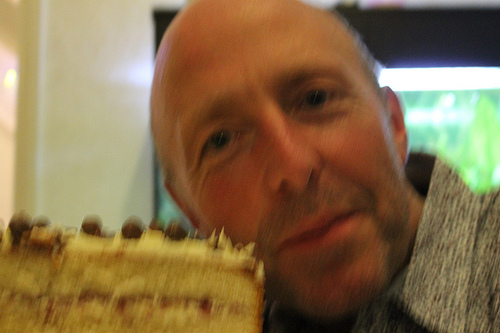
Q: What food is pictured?
A: Cake.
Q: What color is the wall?
A: White.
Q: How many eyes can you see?
A: 2.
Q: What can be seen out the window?
A: Trees.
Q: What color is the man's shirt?
A: Grey.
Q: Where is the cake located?
A: By the man's face.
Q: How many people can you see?
A: 1.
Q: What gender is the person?
A: Male.